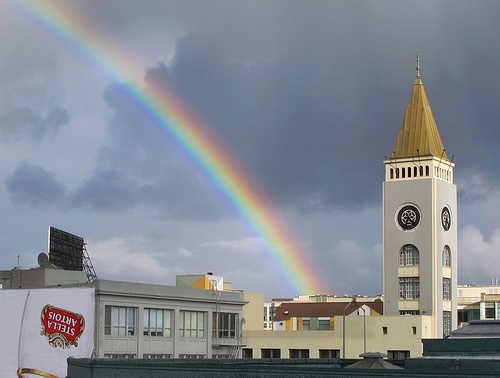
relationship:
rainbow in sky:
[87, 49, 222, 161] [2, 2, 495, 286]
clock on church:
[391, 197, 421, 233] [383, 55, 459, 342]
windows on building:
[101, 302, 140, 341] [10, 279, 247, 369]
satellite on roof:
[33, 249, 54, 267] [13, 266, 248, 304]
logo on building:
[34, 302, 87, 350] [10, 279, 247, 369]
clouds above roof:
[169, 37, 384, 211] [385, 50, 451, 164]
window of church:
[399, 239, 419, 269] [244, 59, 454, 355]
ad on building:
[4, 288, 90, 376] [10, 279, 247, 369]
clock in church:
[391, 197, 421, 233] [383, 55, 459, 342]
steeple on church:
[385, 50, 451, 164] [383, 55, 459, 342]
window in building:
[399, 239, 419, 269] [10, 279, 247, 369]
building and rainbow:
[10, 279, 247, 369] [87, 49, 222, 161]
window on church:
[399, 239, 419, 269] [383, 55, 459, 342]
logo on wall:
[34, 302, 87, 350] [4, 290, 100, 377]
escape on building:
[214, 332, 250, 359] [10, 279, 247, 369]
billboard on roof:
[34, 302, 87, 350] [385, 50, 451, 164]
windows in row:
[101, 302, 140, 341] [105, 299, 249, 348]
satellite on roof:
[33, 249, 54, 267] [385, 50, 451, 164]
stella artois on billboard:
[46, 311, 79, 337] [4, 288, 90, 376]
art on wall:
[34, 302, 87, 350] [4, 290, 100, 377]